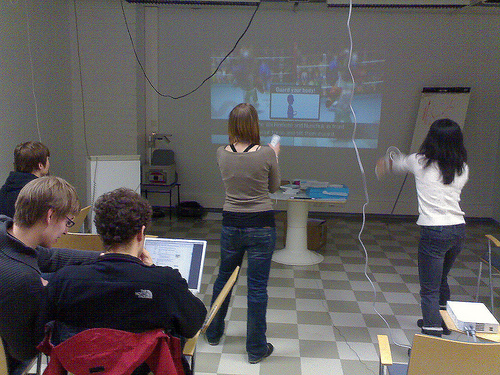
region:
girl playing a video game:
[206, 104, 282, 363]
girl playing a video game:
[374, 119, 470, 335]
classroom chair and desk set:
[376, 333, 498, 373]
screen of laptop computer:
[140, 239, 206, 291]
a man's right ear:
[42, 207, 53, 223]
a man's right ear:
[136, 224, 147, 241]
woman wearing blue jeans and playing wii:
[201, 229, 270, 355]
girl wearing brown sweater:
[211, 137, 278, 222]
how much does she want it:
[395, 153, 473, 223]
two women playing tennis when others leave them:
[207, 91, 472, 347]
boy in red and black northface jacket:
[36, 260, 214, 371]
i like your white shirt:
[390, 150, 468, 236]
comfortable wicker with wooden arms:
[371, 315, 494, 370]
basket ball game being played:
[205, 42, 375, 157]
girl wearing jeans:
[413, 225, 469, 328]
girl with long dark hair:
[409, 115, 471, 186]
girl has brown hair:
[230, 89, 265, 164]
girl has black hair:
[413, 113, 496, 190]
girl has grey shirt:
[215, 143, 262, 202]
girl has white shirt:
[415, 140, 475, 205]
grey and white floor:
[294, 251, 401, 373]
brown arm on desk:
[333, 341, 433, 373]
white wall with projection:
[162, 54, 211, 119]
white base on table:
[280, 182, 326, 277]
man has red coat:
[47, 324, 149, 371]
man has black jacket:
[61, 254, 186, 326]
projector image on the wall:
[208, 46, 382, 151]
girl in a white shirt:
[368, 116, 471, 340]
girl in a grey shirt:
[198, 100, 288, 363]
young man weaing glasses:
[1, 165, 79, 373]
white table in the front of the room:
[233, 173, 354, 275]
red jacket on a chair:
[32, 316, 191, 373]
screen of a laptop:
[137, 230, 207, 297]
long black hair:
[416, 115, 471, 190]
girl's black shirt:
[218, 205, 278, 230]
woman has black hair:
[424, 130, 464, 194]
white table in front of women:
[269, 173, 336, 251]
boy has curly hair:
[81, 186, 193, 261]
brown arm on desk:
[343, 314, 425, 372]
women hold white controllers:
[250, 125, 412, 215]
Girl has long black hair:
[412, 110, 477, 190]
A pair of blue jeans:
[200, 220, 275, 365]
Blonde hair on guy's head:
[10, 170, 80, 250]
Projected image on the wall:
[205, 30, 392, 151]